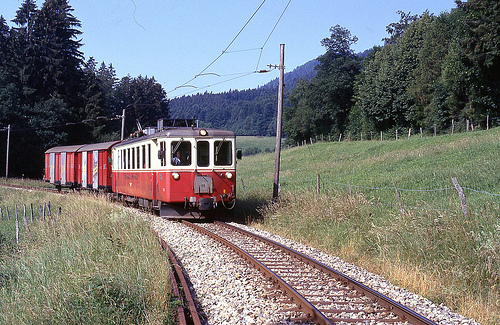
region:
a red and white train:
[24, 90, 249, 226]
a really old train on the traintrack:
[37, 120, 254, 233]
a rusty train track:
[151, 220, 314, 313]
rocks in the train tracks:
[180, 226, 249, 302]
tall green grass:
[351, 156, 472, 224]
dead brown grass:
[349, 226, 456, 286]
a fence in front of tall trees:
[347, 118, 481, 150]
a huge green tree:
[301, 20, 376, 155]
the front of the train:
[113, 115, 255, 227]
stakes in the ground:
[6, 195, 64, 244]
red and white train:
[39, 129, 231, 213]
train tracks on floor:
[5, 171, 432, 323]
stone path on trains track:
[0, 177, 465, 323]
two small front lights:
[171, 168, 237, 180]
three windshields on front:
[169, 137, 236, 166]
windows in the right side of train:
[117, 140, 157, 168]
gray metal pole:
[271, 45, 288, 202]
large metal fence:
[268, 116, 498, 139]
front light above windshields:
[201, 128, 207, 137]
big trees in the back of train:
[0, 0, 184, 177]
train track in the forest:
[195, 228, 375, 323]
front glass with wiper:
[168, 139, 234, 165]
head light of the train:
[166, 166, 238, 185]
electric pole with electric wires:
[269, 38, 285, 218]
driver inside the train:
[172, 146, 187, 171]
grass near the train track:
[44, 217, 144, 324]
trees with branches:
[19, 27, 85, 121]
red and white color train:
[114, 134, 217, 199]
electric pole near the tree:
[3, 121, 19, 178]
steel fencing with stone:
[335, 123, 439, 142]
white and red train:
[46, 125, 235, 214]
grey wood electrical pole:
[276, 44, 283, 201]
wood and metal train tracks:
[197, 219, 424, 323]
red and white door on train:
[154, 143, 168, 204]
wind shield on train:
[172, 140, 234, 165]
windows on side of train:
[118, 145, 153, 167]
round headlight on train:
[171, 170, 181, 180]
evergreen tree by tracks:
[26, 0, 84, 150]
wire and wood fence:
[293, 109, 499, 141]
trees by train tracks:
[278, 4, 498, 140]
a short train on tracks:
[30, 126, 267, 233]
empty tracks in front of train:
[208, 218, 399, 323]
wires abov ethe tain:
[56, 0, 301, 132]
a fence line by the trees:
[285, 121, 498, 157]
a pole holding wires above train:
[253, 29, 309, 206]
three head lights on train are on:
[168, 126, 238, 185]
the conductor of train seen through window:
[167, 142, 190, 177]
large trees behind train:
[16, 3, 181, 154]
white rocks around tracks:
[166, 208, 328, 323]